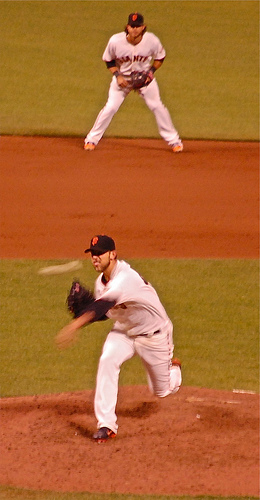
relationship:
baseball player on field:
[67, 14, 190, 169] [8, 25, 248, 493]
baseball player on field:
[45, 225, 201, 450] [8, 25, 248, 493]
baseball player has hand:
[67, 14, 190, 169] [118, 76, 126, 90]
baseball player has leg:
[45, 225, 201, 450] [143, 353, 174, 396]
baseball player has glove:
[45, 225, 201, 450] [67, 285, 86, 314]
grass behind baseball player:
[7, 20, 78, 94] [67, 14, 190, 169]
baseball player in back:
[67, 14, 190, 169] [192, 63, 235, 79]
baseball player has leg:
[67, 14, 190, 169] [148, 90, 171, 135]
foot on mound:
[89, 427, 113, 441] [11, 411, 249, 499]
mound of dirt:
[11, 411, 249, 499] [159, 439, 173, 444]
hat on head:
[128, 14, 141, 25] [126, 15, 154, 32]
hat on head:
[89, 236, 116, 252] [85, 233, 115, 265]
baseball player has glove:
[67, 14, 190, 169] [132, 70, 147, 85]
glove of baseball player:
[67, 285, 86, 314] [67, 14, 190, 169]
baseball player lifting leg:
[45, 225, 201, 450] [99, 344, 109, 419]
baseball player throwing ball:
[45, 225, 201, 450] [24, 255, 82, 275]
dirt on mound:
[159, 439, 173, 444] [11, 411, 249, 499]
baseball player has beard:
[45, 225, 201, 450] [101, 264, 113, 271]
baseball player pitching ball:
[67, 14, 190, 169] [24, 255, 82, 275]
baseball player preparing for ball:
[67, 14, 190, 169] [24, 255, 82, 275]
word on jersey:
[114, 54, 148, 65] [110, 35, 161, 59]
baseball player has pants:
[67, 14, 190, 169] [110, 81, 124, 94]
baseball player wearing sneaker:
[67, 14, 190, 169] [85, 141, 95, 150]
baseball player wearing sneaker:
[67, 14, 190, 169] [173, 142, 184, 152]